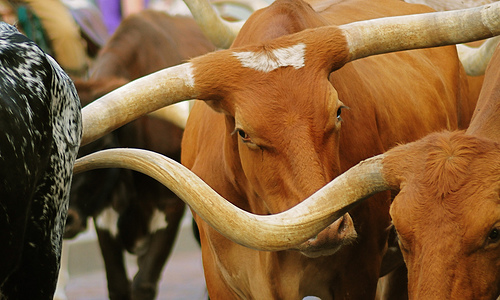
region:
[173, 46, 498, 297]
Two brown cows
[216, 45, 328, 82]
White marking on a cow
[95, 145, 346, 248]
The horn is curved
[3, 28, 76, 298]
Black and white markings on a cow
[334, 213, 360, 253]
A nostril of a cow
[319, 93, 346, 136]
One eye of a cow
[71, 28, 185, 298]
A darker brown cow in the background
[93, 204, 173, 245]
Two white markings on two legs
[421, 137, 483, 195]
The cow's hair is in a circular pattern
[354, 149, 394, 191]
The beginning of the cow's horn.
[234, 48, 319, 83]
white patch on top of the cows head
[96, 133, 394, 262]
long curvy horn on the cow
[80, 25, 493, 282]
long horn cows in the street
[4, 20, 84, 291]
black and white animal in front of the brown cows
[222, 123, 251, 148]
brown cow eye with lashes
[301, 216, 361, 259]
nose of the brown cow with white patch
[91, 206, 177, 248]
white patches on bottom of dark brown cow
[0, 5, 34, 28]
person out of focus watching cows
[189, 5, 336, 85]
bump on the back of the cow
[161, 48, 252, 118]
horn growing out of cows head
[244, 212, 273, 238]
edge of a horn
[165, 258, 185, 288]
part of a floor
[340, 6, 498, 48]
a large curved horn on a bull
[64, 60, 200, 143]
a bulls horn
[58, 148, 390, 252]
a wavy curvy beige horn on a bull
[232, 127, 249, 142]
the eye on a large brown bull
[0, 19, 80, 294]
a black and white speckled tail of a large bull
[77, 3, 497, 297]
a large brown bull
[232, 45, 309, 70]
a white patch of fur on the head of a brown bull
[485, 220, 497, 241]
a black eye on a brown bull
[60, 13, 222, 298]
a large dark brown bull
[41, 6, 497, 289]
several brown cows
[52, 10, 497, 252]
horns of two cows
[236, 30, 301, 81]
white spot on middle cow's head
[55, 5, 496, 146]
horns of middle cow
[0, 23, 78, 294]
black and white speckled side of cow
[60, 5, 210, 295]
dark brown cow in background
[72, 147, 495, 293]
curly horn of brown cow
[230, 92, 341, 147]
eyes of middle cow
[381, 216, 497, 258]
eyes of brown cow on right side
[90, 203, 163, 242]
white spots on dark brown cow